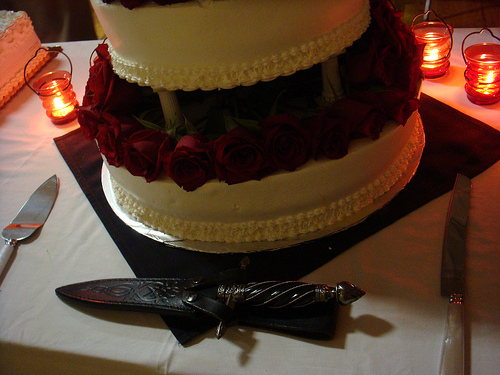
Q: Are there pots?
A: No, there are no pots.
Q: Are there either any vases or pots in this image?
A: No, there are no pots or vases.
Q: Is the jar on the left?
A: Yes, the jar is on the left of the image.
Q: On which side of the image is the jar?
A: The jar is on the left of the image.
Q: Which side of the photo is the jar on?
A: The jar is on the left of the image.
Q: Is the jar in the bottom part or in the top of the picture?
A: The jar is in the top of the image.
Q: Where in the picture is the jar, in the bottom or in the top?
A: The jar is in the top of the image.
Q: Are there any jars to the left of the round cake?
A: Yes, there is a jar to the left of the cake.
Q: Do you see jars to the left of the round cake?
A: Yes, there is a jar to the left of the cake.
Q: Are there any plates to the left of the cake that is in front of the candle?
A: No, there is a jar to the left of the cake.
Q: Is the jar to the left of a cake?
A: Yes, the jar is to the left of a cake.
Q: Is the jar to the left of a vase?
A: No, the jar is to the left of a cake.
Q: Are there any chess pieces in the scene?
A: No, there are no chess pieces.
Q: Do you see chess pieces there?
A: No, there are no chess pieces.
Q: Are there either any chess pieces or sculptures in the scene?
A: No, there are no chess pieces or sculptures.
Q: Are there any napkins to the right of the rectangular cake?
A: Yes, there is a napkin to the right of the cake.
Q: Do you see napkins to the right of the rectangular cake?
A: Yes, there is a napkin to the right of the cake.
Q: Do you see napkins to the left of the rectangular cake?
A: No, the napkin is to the right of the cake.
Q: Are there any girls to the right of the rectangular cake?
A: No, there is a napkin to the right of the cake.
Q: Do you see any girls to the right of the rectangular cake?
A: No, there is a napkin to the right of the cake.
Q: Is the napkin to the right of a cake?
A: Yes, the napkin is to the right of a cake.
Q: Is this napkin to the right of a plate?
A: No, the napkin is to the right of a cake.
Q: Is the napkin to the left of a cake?
A: No, the napkin is to the right of a cake.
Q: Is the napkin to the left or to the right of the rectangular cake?
A: The napkin is to the right of the cake.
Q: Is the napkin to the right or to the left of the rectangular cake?
A: The napkin is to the right of the cake.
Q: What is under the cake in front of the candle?
A: The napkin is under the cake.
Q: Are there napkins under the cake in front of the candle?
A: Yes, there is a napkin under the cake.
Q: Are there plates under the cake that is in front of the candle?
A: No, there is a napkin under the cake.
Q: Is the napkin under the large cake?
A: Yes, the napkin is under the cake.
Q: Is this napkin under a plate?
A: No, the napkin is under the cake.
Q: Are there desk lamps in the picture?
A: No, there are no desk lamps.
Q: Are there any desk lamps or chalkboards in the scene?
A: No, there are no desk lamps or chalkboards.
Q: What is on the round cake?
A: The rose is on the cake.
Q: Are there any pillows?
A: No, there are no pillows.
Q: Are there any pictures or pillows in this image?
A: No, there are no pillows or pictures.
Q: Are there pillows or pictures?
A: No, there are no pillows or pictures.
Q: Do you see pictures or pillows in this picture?
A: No, there are no pillows or pictures.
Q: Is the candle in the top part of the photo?
A: Yes, the candle is in the top of the image.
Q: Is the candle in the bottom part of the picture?
A: No, the candle is in the top of the image.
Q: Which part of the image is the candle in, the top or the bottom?
A: The candle is in the top of the image.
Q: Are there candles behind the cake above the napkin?
A: Yes, there is a candle behind the cake.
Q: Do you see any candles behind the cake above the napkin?
A: Yes, there is a candle behind the cake.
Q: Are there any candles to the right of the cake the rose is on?
A: Yes, there is a candle to the right of the cake.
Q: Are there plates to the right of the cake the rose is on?
A: No, there is a candle to the right of the cake.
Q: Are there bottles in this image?
A: No, there are no bottles.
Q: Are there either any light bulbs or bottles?
A: No, there are no bottles or light bulbs.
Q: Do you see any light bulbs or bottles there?
A: No, there are no bottles or light bulbs.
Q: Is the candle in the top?
A: Yes, the candle is in the top of the image.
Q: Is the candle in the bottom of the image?
A: No, the candle is in the top of the image.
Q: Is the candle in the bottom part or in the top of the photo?
A: The candle is in the top of the image.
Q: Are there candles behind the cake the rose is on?
A: Yes, there is a candle behind the cake.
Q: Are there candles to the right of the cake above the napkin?
A: Yes, there is a candle to the right of the cake.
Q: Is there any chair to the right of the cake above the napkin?
A: No, there is a candle to the right of the cake.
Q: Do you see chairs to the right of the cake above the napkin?
A: No, there is a candle to the right of the cake.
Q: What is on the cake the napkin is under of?
A: The rose is on the cake.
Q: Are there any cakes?
A: Yes, there is a cake.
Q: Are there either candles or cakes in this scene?
A: Yes, there is a cake.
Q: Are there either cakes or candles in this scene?
A: Yes, there is a cake.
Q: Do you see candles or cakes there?
A: Yes, there is a cake.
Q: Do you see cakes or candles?
A: Yes, there is a cake.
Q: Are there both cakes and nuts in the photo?
A: No, there is a cake but no nuts.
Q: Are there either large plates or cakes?
A: Yes, there is a large cake.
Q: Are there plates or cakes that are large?
A: Yes, the cake is large.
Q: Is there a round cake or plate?
A: Yes, there is a round cake.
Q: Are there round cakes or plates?
A: Yes, there is a round cake.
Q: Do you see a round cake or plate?
A: Yes, there is a round cake.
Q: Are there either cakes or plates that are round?
A: Yes, the cake is round.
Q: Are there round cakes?
A: Yes, there is a round cake.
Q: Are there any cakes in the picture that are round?
A: Yes, there is a cake that is round.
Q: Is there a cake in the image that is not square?
A: Yes, there is a round cake.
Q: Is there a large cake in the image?
A: Yes, there is a large cake.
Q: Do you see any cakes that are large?
A: Yes, there is a cake that is large.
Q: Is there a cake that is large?
A: Yes, there is a cake that is large.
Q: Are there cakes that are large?
A: Yes, there is a cake that is large.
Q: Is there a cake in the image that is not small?
A: Yes, there is a large cake.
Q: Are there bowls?
A: No, there are no bowls.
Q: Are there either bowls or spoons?
A: No, there are no bowls or spoons.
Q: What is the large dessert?
A: The dessert is a cake.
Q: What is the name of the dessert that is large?
A: The dessert is a cake.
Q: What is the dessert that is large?
A: The dessert is a cake.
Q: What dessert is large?
A: The dessert is a cake.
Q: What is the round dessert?
A: The dessert is a cake.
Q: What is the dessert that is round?
A: The dessert is a cake.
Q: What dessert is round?
A: The dessert is a cake.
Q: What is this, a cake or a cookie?
A: This is a cake.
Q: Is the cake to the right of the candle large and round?
A: Yes, the cake is large and round.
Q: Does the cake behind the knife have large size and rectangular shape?
A: No, the cake is large but round.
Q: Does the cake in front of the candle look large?
A: Yes, the cake is large.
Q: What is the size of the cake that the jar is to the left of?
A: The cake is large.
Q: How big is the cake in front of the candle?
A: The cake is large.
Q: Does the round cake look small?
A: No, the cake is large.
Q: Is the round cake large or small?
A: The cake is large.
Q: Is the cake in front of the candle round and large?
A: Yes, the cake is round and large.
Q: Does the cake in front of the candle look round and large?
A: Yes, the cake is round and large.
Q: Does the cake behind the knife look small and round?
A: No, the cake is round but large.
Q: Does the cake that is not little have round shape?
A: Yes, the cake is round.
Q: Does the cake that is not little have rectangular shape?
A: No, the cake is round.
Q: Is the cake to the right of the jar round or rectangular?
A: The cake is round.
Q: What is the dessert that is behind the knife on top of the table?
A: The dessert is a cake.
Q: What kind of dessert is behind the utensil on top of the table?
A: The dessert is a cake.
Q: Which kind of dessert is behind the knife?
A: The dessert is a cake.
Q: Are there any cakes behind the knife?
A: Yes, there is a cake behind the knife.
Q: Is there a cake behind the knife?
A: Yes, there is a cake behind the knife.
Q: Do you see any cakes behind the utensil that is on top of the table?
A: Yes, there is a cake behind the knife.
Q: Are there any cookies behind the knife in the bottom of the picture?
A: No, there is a cake behind the knife.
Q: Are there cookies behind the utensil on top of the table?
A: No, there is a cake behind the knife.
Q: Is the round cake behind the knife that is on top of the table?
A: Yes, the cake is behind the knife.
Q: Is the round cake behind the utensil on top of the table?
A: Yes, the cake is behind the knife.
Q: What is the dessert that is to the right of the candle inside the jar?
A: The dessert is a cake.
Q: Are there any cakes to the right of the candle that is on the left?
A: Yes, there is a cake to the right of the candle.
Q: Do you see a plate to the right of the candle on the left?
A: No, there is a cake to the right of the candle.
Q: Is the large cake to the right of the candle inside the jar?
A: Yes, the cake is to the right of the candle.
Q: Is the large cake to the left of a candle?
A: No, the cake is to the right of a candle.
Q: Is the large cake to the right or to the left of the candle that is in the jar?
A: The cake is to the right of the candle.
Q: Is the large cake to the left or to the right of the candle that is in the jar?
A: The cake is to the right of the candle.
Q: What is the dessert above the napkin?
A: The dessert is a cake.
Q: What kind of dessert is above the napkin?
A: The dessert is a cake.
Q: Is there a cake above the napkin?
A: Yes, there is a cake above the napkin.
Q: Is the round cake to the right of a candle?
A: No, the cake is to the left of a candle.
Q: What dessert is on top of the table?
A: The dessert is a cake.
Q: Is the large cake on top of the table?
A: Yes, the cake is on top of the table.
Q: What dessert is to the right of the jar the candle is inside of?
A: The dessert is a cake.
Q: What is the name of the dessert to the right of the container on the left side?
A: The dessert is a cake.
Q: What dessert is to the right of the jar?
A: The dessert is a cake.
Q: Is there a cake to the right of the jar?
A: Yes, there is a cake to the right of the jar.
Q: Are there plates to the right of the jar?
A: No, there is a cake to the right of the jar.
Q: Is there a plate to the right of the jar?
A: No, there is a cake to the right of the jar.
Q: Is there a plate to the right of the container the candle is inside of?
A: No, there is a cake to the right of the jar.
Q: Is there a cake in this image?
A: Yes, there is a cake.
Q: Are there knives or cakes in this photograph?
A: Yes, there is a cake.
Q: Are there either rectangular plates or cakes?
A: Yes, there is a rectangular cake.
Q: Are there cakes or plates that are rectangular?
A: Yes, the cake is rectangular.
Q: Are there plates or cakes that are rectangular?
A: Yes, the cake is rectangular.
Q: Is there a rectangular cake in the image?
A: Yes, there is a rectangular cake.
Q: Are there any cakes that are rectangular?
A: Yes, there is a rectangular cake.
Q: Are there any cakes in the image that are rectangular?
A: Yes, there is a cake that is rectangular.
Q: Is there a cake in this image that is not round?
A: Yes, there is a rectangular cake.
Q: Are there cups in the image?
A: No, there are no cups.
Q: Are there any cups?
A: No, there are no cups.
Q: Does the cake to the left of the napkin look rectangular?
A: Yes, the cake is rectangular.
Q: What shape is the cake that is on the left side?
A: The cake is rectangular.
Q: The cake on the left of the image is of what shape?
A: The cake is rectangular.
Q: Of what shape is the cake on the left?
A: The cake is rectangular.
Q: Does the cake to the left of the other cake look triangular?
A: No, the cake is rectangular.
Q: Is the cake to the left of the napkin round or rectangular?
A: The cake is rectangular.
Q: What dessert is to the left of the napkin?
A: The dessert is a cake.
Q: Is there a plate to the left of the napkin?
A: No, there is a cake to the left of the napkin.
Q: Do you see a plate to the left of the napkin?
A: No, there is a cake to the left of the napkin.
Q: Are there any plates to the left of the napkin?
A: No, there is a cake to the left of the napkin.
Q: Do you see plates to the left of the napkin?
A: No, there is a cake to the left of the napkin.